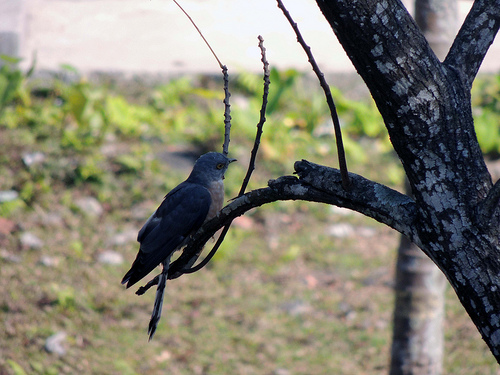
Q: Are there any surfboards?
A: No, there are no surfboards.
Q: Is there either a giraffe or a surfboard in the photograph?
A: No, there are no surfboards or giraffes.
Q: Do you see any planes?
A: No, there are no planes.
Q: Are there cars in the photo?
A: No, there are no cars.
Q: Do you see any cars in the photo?
A: No, there are no cars.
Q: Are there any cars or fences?
A: No, there are no cars or fences.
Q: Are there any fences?
A: No, there are no fences.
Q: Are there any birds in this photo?
A: Yes, there is a bird.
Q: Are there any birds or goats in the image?
A: Yes, there is a bird.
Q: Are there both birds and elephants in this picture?
A: No, there is a bird but no elephants.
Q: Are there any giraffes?
A: No, there are no giraffes.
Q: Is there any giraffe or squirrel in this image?
A: No, there are no giraffes or squirrels.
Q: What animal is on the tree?
A: The bird is on the tree.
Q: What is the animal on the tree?
A: The animal is a bird.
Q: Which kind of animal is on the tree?
A: The animal is a bird.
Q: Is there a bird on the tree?
A: Yes, there is a bird on the tree.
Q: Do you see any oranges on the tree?
A: No, there is a bird on the tree.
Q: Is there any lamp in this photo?
A: No, there are no lamps.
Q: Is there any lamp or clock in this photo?
A: No, there are no lamps or clocks.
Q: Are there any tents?
A: No, there are no tents.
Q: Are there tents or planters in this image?
A: No, there are no tents or planters.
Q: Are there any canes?
A: No, there are no canes.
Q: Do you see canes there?
A: No, there are no canes.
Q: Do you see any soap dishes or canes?
A: No, there are no canes or soap dishes.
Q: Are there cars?
A: No, there are no cars.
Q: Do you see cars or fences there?
A: No, there are no cars or fences.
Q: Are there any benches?
A: No, there are no benches.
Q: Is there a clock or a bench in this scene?
A: No, there are no benches or clocks.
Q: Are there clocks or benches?
A: No, there are no benches or clocks.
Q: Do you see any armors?
A: No, there are no armors.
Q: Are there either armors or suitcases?
A: No, there are no armors or suitcases.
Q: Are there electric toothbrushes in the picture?
A: No, there are no electric toothbrushes.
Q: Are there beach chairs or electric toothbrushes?
A: No, there are no electric toothbrushes or beach chairs.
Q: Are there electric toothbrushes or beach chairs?
A: No, there are no electric toothbrushes or beach chairs.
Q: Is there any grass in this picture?
A: Yes, there is grass.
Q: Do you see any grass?
A: Yes, there is grass.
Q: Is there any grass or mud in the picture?
A: Yes, there is grass.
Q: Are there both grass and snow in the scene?
A: No, there is grass but no snow.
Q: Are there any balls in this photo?
A: No, there are no balls.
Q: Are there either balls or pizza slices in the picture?
A: No, there are no balls or pizza slices.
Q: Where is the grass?
A: The grass is on the ground.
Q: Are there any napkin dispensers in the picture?
A: No, there are no napkin dispensers.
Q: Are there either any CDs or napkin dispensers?
A: No, there are no napkin dispensers or cds.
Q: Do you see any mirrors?
A: No, there are no mirrors.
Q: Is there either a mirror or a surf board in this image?
A: No, there are no mirrors or surfboards.